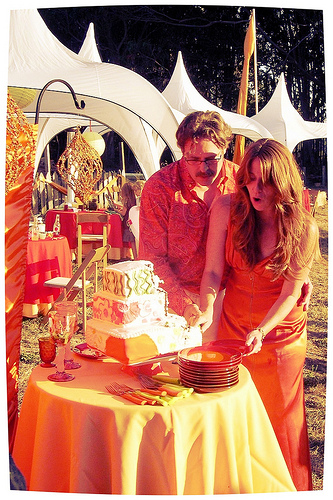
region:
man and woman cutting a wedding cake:
[96, 82, 309, 444]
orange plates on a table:
[168, 313, 257, 410]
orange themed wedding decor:
[1, 24, 319, 450]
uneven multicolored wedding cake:
[69, 240, 212, 386]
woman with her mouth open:
[216, 87, 332, 465]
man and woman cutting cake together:
[76, 100, 328, 412]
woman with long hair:
[222, 108, 313, 399]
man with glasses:
[130, 76, 246, 323]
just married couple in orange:
[66, 64, 307, 409]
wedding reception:
[15, 37, 311, 448]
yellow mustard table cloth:
[34, 382, 259, 477]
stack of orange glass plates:
[173, 344, 246, 397]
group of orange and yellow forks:
[97, 375, 186, 400]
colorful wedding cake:
[84, 247, 178, 352]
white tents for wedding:
[47, 17, 268, 103]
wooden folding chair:
[47, 241, 95, 299]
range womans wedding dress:
[221, 194, 321, 404]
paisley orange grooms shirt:
[136, 170, 227, 292]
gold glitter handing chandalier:
[39, 132, 137, 211]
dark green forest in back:
[127, 22, 314, 68]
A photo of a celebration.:
[1, 0, 330, 497]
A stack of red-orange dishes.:
[174, 344, 244, 393]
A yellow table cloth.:
[94, 394, 286, 496]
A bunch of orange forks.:
[96, 369, 191, 405]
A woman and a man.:
[140, 110, 328, 498]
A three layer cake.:
[86, 262, 202, 365]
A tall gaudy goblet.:
[44, 305, 75, 382]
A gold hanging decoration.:
[56, 131, 102, 199]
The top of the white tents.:
[2, 0, 331, 139]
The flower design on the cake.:
[97, 300, 116, 319]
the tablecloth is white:
[43, 384, 227, 495]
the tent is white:
[17, 19, 145, 120]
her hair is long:
[236, 122, 304, 267]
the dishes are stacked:
[164, 331, 251, 392]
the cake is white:
[55, 233, 201, 359]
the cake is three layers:
[68, 242, 210, 393]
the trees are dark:
[176, 10, 235, 87]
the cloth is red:
[39, 195, 125, 253]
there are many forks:
[94, 370, 181, 413]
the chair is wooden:
[42, 234, 109, 351]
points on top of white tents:
[53, 19, 302, 135]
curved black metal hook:
[15, 58, 87, 121]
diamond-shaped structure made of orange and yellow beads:
[48, 122, 97, 205]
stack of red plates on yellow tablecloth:
[168, 334, 241, 439]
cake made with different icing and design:
[76, 256, 196, 357]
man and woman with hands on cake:
[132, 110, 312, 345]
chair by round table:
[29, 218, 102, 320]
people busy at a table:
[103, 176, 140, 258]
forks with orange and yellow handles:
[102, 363, 190, 413]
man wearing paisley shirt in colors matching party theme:
[136, 116, 224, 313]